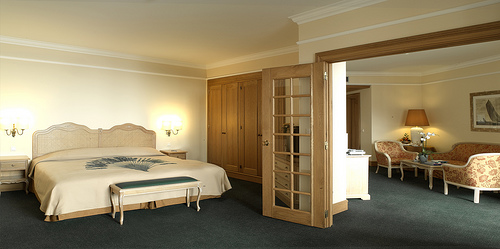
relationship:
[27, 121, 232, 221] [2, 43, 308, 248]
bed in bedroom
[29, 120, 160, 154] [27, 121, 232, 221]
headboard on bed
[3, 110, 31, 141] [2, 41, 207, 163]
light on wall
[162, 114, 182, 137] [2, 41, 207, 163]
light on wall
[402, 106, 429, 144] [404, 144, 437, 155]
lamp on table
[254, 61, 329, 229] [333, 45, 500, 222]
door leading to room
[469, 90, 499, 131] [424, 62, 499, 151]
painting on wall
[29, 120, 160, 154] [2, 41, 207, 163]
headboard against wall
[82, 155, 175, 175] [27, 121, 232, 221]
design on bed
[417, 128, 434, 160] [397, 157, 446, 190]
flowers on table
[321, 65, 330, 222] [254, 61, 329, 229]
hinges on door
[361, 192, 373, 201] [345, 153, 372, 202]
foot on dresser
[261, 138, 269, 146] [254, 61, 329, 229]
handle on door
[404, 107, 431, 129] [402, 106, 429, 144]
lampshade on lamp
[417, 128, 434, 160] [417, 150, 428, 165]
flowers in vase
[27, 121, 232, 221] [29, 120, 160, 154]
bed has headboard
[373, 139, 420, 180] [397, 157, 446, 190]
chair next to table